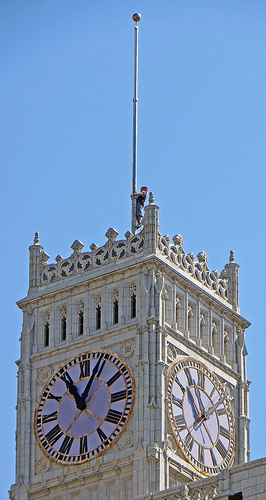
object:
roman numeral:
[39, 408, 59, 425]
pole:
[129, 23, 139, 237]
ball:
[132, 11, 142, 23]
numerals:
[210, 448, 217, 467]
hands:
[192, 378, 206, 417]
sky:
[0, 0, 266, 500]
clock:
[32, 349, 135, 468]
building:
[7, 12, 265, 500]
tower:
[6, 9, 266, 500]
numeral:
[78, 359, 90, 380]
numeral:
[95, 359, 105, 380]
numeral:
[105, 370, 121, 388]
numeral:
[110, 388, 126, 403]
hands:
[59, 375, 85, 410]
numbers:
[175, 374, 186, 395]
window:
[130, 292, 137, 320]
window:
[176, 302, 180, 325]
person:
[130, 185, 148, 225]